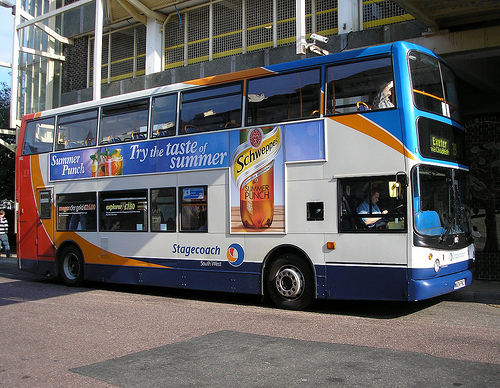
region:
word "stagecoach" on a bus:
[168, 240, 223, 257]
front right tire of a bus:
[254, 235, 318, 307]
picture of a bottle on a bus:
[231, 126, 292, 237]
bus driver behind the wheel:
[348, 185, 391, 235]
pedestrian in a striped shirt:
[0, 202, 13, 262]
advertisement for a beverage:
[50, 112, 338, 247]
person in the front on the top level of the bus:
[366, 75, 398, 115]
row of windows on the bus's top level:
[20, 62, 396, 138]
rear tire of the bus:
[50, 236, 87, 289]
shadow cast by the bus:
[41, 271, 444, 321]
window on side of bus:
[322, 62, 400, 111]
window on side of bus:
[246, 72, 317, 129]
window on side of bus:
[176, 93, 243, 132]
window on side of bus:
[149, 90, 175, 135]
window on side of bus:
[103, 107, 147, 145]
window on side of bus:
[53, 109, 97, 149]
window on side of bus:
[21, 116, 53, 152]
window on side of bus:
[56, 195, 92, 235]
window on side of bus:
[151, 189, 176, 228]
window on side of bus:
[329, 177, 403, 239]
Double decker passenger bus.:
[7, 67, 473, 319]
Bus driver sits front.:
[332, 175, 420, 250]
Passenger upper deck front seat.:
[343, 64, 415, 126]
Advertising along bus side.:
[46, 132, 239, 179]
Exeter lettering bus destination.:
[402, 116, 462, 167]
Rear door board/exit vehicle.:
[25, 176, 60, 256]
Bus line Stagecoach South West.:
[152, 233, 248, 269]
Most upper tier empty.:
[60, 84, 301, 147]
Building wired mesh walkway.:
[74, 0, 292, 68]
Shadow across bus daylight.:
[0, 63, 268, 334]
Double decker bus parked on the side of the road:
[9, 50, 489, 315]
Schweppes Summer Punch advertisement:
[215, 116, 312, 251]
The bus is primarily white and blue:
[3, 39, 485, 320]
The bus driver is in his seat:
[345, 180, 410, 245]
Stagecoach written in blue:
[154, 235, 232, 260]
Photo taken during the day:
[7, 10, 490, 377]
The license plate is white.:
[445, 270, 470, 292]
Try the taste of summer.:
[121, 135, 241, 168]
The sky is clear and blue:
[0, 5, 37, 101]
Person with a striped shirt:
[0, 211, 15, 259]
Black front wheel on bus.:
[260, 247, 312, 309]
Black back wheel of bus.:
[53, 236, 88, 287]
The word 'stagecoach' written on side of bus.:
[165, 240, 232, 254]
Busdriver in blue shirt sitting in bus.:
[354, 190, 389, 232]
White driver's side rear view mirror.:
[385, 170, 401, 199]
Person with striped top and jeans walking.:
[1, 207, 15, 256]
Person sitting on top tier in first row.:
[360, 79, 396, 115]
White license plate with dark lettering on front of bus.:
[451, 277, 466, 291]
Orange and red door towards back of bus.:
[33, 181, 56, 263]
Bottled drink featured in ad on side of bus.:
[232, 124, 276, 231]